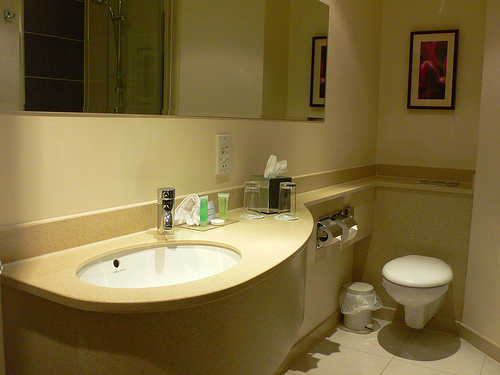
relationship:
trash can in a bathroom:
[334, 275, 388, 337] [3, 40, 495, 373]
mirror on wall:
[19, 2, 329, 122] [8, 122, 210, 176]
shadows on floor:
[294, 339, 341, 373] [279, 315, 499, 374]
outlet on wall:
[214, 133, 232, 183] [3, 0, 378, 373]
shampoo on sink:
[197, 192, 209, 224] [71, 219, 244, 287]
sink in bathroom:
[74, 232, 254, 292] [3, 0, 494, 374]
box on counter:
[245, 173, 293, 218] [7, 197, 312, 317]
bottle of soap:
[197, 196, 209, 229] [202, 202, 205, 223]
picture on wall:
[403, 30, 458, 112] [373, 0, 485, 305]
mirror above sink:
[19, 2, 329, 122] [73, 240, 240, 289]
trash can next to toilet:
[338, 280, 378, 333] [379, 251, 454, 327]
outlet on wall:
[215, 133, 232, 178] [0, 1, 383, 227]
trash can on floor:
[338, 280, 378, 333] [287, 302, 497, 371]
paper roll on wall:
[319, 224, 342, 248] [308, 194, 365, 339]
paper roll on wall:
[340, 219, 362, 240] [308, 194, 365, 339]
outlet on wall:
[214, 133, 232, 183] [0, 1, 383, 227]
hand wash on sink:
[212, 190, 235, 222] [78, 237, 243, 290]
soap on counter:
[210, 214, 225, 227] [0, 195, 315, 309]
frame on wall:
[405, 30, 462, 111] [374, 3, 486, 174]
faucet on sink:
[153, 177, 185, 248] [60, 170, 302, 283]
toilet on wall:
[383, 257, 454, 335] [352, 2, 488, 326]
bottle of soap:
[218, 190, 228, 224] [185, 182, 251, 241]